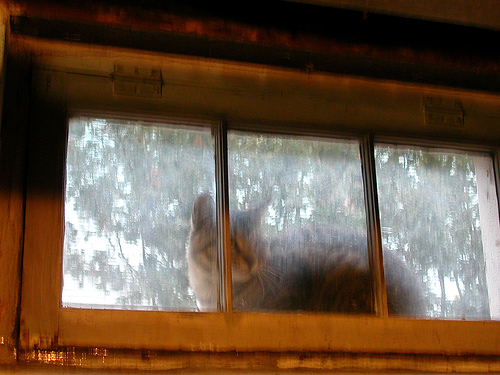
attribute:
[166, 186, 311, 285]
cat — sitting, gray, looking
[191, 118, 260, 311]
dividers — wood, between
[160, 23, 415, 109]
boarder — brown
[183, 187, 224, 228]
ears — grey, sticking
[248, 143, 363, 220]
tree — green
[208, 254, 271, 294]
whiskers — white, long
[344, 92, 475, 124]
hinge — metal, used, securing, inside, screwed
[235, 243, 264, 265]
nose — dark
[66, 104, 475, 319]
windows — paned, rowed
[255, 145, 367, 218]
trees — behind, thick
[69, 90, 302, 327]
window — closed, glass, wooden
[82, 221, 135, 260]
sky — behind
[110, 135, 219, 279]
pane — glass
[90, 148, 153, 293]
light — reflecting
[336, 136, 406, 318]
rod — seperating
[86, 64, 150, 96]
rivet — small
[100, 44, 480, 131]
rivets — small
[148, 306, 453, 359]
frame — wooden